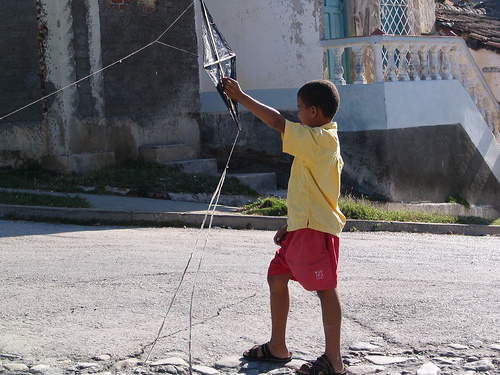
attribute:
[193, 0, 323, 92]
wall — worn, white, painted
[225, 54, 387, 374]
boy — little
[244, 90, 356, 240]
shirt — short sleeve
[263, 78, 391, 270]
boy — little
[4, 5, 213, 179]
wall — faded, black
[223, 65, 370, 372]
boy — little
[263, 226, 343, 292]
shorts — red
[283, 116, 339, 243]
shirt — yellow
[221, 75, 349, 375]
boy — little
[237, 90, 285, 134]
arm — raised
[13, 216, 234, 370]
concrete — gray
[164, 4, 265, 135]
kite — black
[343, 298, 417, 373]
rocks — grey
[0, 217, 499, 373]
ground — cement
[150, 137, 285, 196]
steps — three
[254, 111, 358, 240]
shirt — yellow 